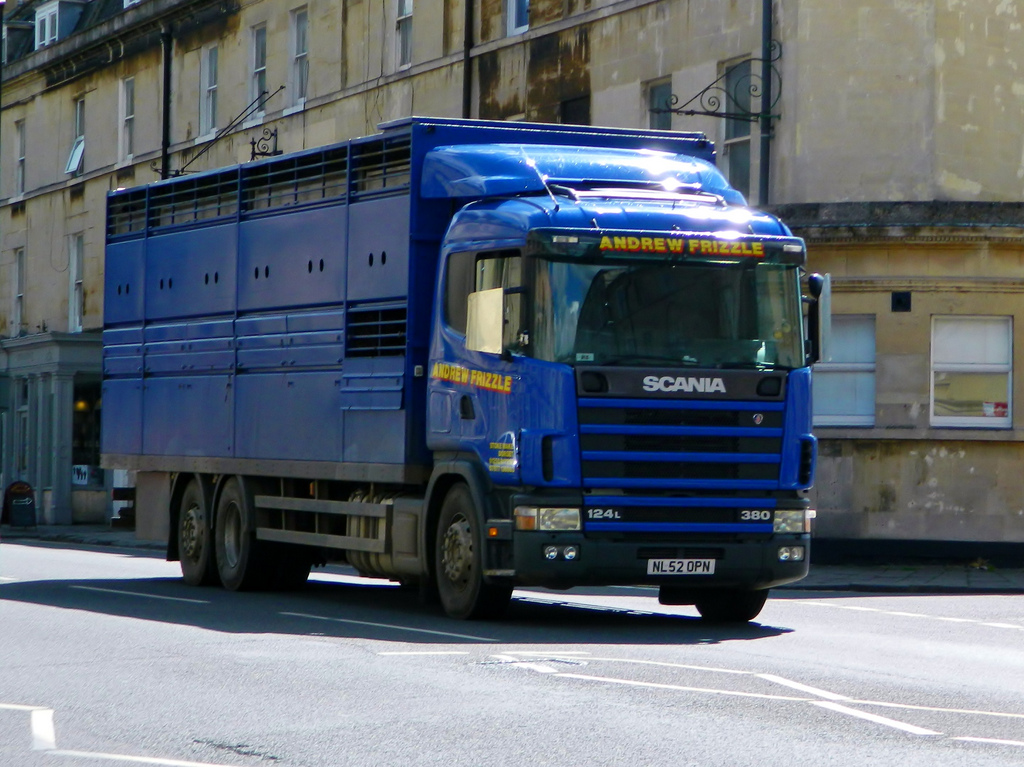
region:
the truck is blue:
[82, 107, 835, 645]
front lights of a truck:
[502, 489, 825, 546]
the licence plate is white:
[637, 546, 724, 585]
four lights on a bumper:
[498, 527, 830, 594]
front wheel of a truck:
[416, 467, 519, 629]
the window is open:
[56, 82, 94, 203]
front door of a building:
[0, 327, 114, 537]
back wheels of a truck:
[148, 461, 326, 610]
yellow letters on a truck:
[585, 210, 778, 274]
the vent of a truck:
[328, 280, 427, 375]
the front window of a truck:
[429, 214, 822, 392]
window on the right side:
[799, 245, 844, 388]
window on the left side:
[446, 270, 542, 372]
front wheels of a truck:
[411, 470, 785, 642]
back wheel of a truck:
[152, 467, 327, 610]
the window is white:
[803, 298, 890, 441]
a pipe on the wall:
[742, 0, 790, 209]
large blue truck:
[93, 116, 836, 633]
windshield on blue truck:
[524, 254, 812, 372]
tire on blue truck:
[427, 489, 519, 616]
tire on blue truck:
[209, 476, 276, 591]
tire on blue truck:
[171, 476, 222, 584]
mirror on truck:
[462, 280, 510, 363]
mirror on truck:
[798, 261, 833, 364]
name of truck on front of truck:
[636, 369, 726, 401]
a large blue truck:
[94, 114, 834, 621]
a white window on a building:
[929, 312, 1016, 430]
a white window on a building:
[815, 309, 880, 428]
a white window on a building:
[290, 2, 323, 114]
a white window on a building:
[249, 21, 279, 123]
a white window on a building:
[198, 41, 225, 141]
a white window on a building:
[114, 78, 141, 162]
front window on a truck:
[451, 236, 824, 386]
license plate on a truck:
[648, 553, 719, 580]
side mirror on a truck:
[462, 279, 535, 356]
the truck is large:
[98, 117, 829, 624]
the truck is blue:
[96, 110, 824, 624]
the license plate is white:
[645, 553, 719, 574]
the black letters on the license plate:
[645, 554, 719, 577]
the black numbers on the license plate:
[645, 556, 718, 576]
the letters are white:
[640, 373, 724, 396]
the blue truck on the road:
[2, 110, 1020, 760]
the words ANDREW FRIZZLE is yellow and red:
[596, 231, 764, 257]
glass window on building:
[931, 316, 1009, 428]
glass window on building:
[803, 309, 874, 427]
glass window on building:
[717, 62, 752, 203]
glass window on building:
[506, 2, 530, 31]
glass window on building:
[386, 4, 412, 62]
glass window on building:
[293, 6, 312, 106]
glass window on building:
[250, 13, 270, 131]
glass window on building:
[202, 42, 222, 147]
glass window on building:
[119, 79, 145, 175]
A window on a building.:
[928, 315, 1006, 439]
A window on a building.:
[803, 305, 889, 426]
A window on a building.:
[716, 59, 749, 189]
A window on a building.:
[642, 83, 687, 126]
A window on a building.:
[552, 96, 594, 129]